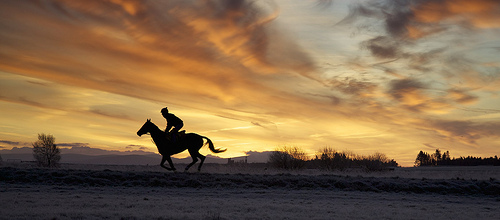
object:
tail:
[200, 136, 227, 153]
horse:
[137, 119, 227, 173]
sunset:
[3, 101, 500, 167]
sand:
[3, 185, 498, 220]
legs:
[170, 126, 182, 135]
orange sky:
[0, 0, 500, 168]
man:
[161, 107, 185, 135]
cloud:
[0, 0, 500, 166]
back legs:
[192, 148, 207, 172]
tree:
[414, 149, 500, 167]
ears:
[147, 119, 149, 122]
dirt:
[0, 166, 500, 220]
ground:
[0, 162, 500, 220]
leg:
[160, 157, 170, 169]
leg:
[166, 156, 179, 173]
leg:
[184, 149, 199, 172]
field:
[0, 154, 500, 220]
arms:
[165, 118, 173, 131]